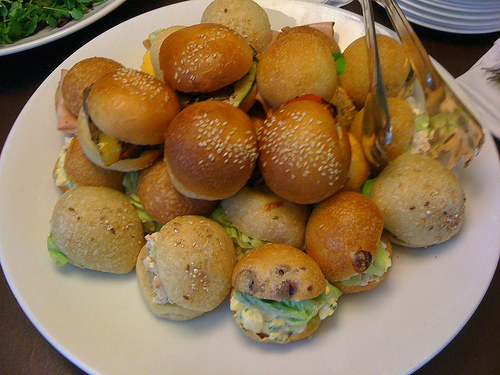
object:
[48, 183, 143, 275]
bread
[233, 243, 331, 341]
bread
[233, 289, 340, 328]
lettuce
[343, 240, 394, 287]
lettuce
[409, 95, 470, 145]
lettuce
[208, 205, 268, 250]
lettuce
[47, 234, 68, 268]
lettuce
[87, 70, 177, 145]
bread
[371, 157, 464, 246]
bread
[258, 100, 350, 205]
bread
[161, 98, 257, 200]
bread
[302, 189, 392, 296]
bread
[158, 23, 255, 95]
bread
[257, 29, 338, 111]
bread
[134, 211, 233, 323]
sandwich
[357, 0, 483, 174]
tongs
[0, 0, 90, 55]
green lettuce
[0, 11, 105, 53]
plate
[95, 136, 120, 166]
cheese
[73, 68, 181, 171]
bun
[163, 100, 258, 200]
bun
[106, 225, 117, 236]
speck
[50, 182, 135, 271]
bun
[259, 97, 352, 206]
bun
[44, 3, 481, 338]
food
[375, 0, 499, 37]
plates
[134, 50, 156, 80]
traffic light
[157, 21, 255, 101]
bun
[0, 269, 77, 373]
table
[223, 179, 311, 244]
sandwich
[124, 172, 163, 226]
lettuce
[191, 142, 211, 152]
seeds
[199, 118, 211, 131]
seeds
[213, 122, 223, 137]
seeds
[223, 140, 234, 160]
seeds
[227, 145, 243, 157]
seeds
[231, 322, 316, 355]
shadow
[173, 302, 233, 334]
shadow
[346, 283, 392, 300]
shadow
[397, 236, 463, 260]
shadow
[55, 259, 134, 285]
shadow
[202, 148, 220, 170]
seeds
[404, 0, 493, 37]
stack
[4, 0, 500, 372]
plate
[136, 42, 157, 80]
cheese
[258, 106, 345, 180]
seeds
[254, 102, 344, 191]
specks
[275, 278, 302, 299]
dot